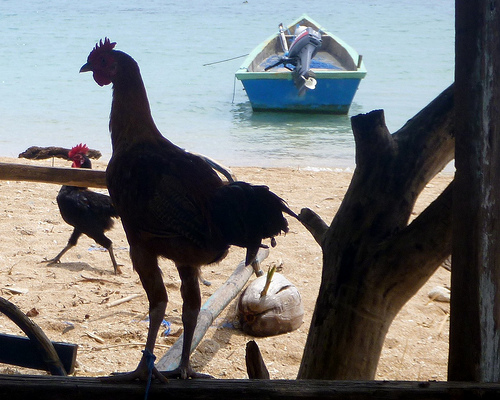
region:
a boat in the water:
[236, 20, 363, 109]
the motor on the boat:
[286, 22, 318, 84]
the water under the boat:
[16, 7, 421, 170]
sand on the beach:
[6, 150, 483, 397]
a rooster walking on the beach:
[56, 138, 175, 277]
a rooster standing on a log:
[86, 48, 278, 381]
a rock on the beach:
[246, 275, 306, 332]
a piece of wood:
[15, 354, 436, 399]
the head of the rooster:
[76, 43, 136, 83]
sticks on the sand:
[55, 272, 120, 319]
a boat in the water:
[194, 16, 494, 169]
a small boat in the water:
[207, 29, 495, 161]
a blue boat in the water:
[202, 3, 464, 224]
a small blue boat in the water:
[168, 31, 474, 205]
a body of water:
[127, 8, 466, 136]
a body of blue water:
[126, 13, 466, 185]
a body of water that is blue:
[114, 1, 497, 154]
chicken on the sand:
[49, 58, 499, 398]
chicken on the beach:
[19, 41, 331, 394]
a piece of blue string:
[137, 343, 161, 390]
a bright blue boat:
[232, 5, 365, 115]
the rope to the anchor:
[207, 49, 246, 64]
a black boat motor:
[278, 25, 325, 92]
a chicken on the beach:
[41, 136, 131, 278]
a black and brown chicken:
[76, 28, 298, 390]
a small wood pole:
[353, 52, 366, 66]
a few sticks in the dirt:
[83, 266, 143, 321]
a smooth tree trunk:
[311, 104, 447, 381]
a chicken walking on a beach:
[40, 133, 100, 293]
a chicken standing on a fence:
[60, 27, 248, 398]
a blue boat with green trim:
[226, 18, 386, 133]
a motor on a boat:
[283, 24, 333, 96]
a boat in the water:
[206, 13, 374, 118]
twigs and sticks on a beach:
[75, 287, 134, 337]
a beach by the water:
[205, 140, 343, 222]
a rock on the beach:
[416, 276, 452, 321]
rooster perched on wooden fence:
[79, 40, 270, 395]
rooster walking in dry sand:
[43, 143, 129, 273]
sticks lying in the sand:
[42, 270, 153, 345]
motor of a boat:
[286, 25, 322, 94]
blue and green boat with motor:
[234, 12, 366, 114]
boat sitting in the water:
[233, 13, 365, 118]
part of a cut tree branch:
[240, 86, 457, 379]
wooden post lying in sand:
[148, 245, 273, 372]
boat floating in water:
[5, 5, 451, 167]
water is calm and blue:
[3, 3, 458, 156]